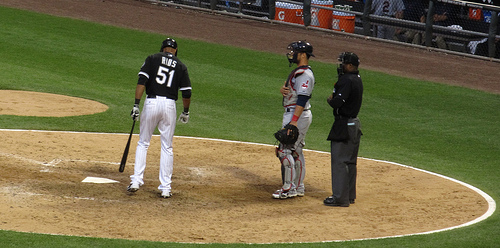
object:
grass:
[0, 6, 497, 248]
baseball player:
[126, 37, 192, 198]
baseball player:
[271, 40, 316, 199]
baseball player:
[323, 51, 363, 207]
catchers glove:
[274, 122, 300, 145]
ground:
[380, 123, 412, 153]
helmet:
[160, 37, 178, 57]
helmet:
[286, 39, 315, 67]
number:
[155, 66, 175, 87]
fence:
[145, 0, 500, 62]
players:
[271, 41, 362, 206]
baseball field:
[0, 0, 500, 248]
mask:
[288, 47, 296, 59]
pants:
[275, 111, 312, 190]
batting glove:
[178, 112, 190, 124]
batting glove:
[130, 104, 140, 121]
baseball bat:
[118, 120, 135, 172]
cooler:
[331, 11, 357, 34]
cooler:
[309, 0, 332, 29]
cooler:
[273, 1, 303, 25]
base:
[81, 177, 120, 184]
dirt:
[0, 129, 493, 246]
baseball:
[114, 34, 365, 215]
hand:
[130, 104, 140, 121]